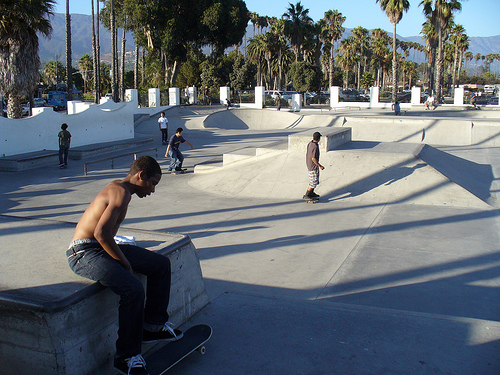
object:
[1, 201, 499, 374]
street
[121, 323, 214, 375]
skateboard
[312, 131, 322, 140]
cap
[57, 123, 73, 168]
boys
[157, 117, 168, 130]
shirt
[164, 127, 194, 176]
teenager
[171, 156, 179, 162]
knees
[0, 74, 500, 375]
park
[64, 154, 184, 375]
boy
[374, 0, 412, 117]
trees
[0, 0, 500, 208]
background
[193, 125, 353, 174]
stairs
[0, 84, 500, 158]
plinths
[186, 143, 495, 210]
ramps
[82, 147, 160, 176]
rail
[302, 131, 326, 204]
boy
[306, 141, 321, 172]
shirt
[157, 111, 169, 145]
boy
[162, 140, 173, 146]
skateboard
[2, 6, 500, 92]
hills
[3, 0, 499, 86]
distance